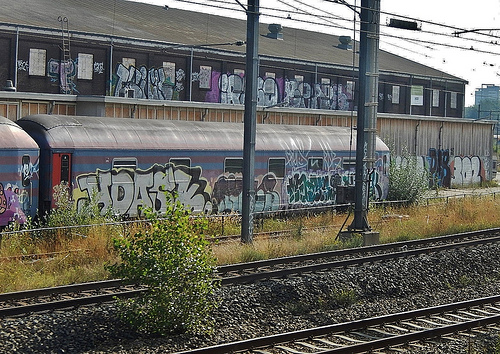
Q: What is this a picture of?
A: Train tracks.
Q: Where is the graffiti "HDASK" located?
A: The trailer.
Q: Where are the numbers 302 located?
A: The noise barrier.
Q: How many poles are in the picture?
A: Two.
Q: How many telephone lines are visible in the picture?
A: Three.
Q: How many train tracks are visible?
A: Two.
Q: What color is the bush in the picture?
A: Green.